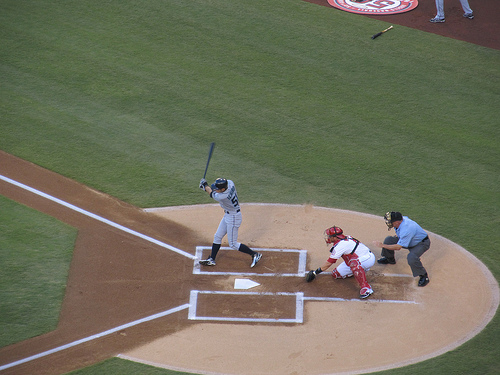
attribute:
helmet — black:
[209, 177, 229, 189]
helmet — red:
[321, 227, 347, 241]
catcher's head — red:
[320, 225, 351, 246]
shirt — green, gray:
[201, 175, 242, 215]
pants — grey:
[211, 211, 246, 256]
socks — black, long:
[205, 241, 259, 268]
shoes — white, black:
[195, 252, 267, 275]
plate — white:
[229, 268, 266, 297]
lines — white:
[189, 239, 312, 282]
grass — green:
[1, 194, 79, 357]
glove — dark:
[300, 264, 314, 287]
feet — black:
[379, 249, 431, 290]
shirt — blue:
[391, 217, 429, 252]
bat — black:
[201, 137, 218, 188]